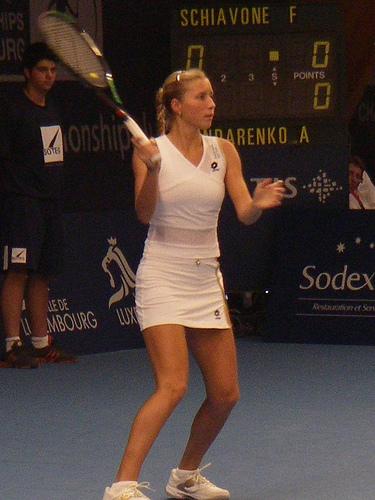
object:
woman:
[94, 67, 285, 497]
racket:
[32, 6, 163, 173]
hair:
[155, 67, 202, 135]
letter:
[300, 124, 309, 144]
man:
[3, 46, 77, 367]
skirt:
[132, 251, 233, 332]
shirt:
[0, 89, 71, 205]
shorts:
[0, 202, 58, 275]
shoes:
[36, 340, 81, 366]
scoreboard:
[169, 7, 352, 231]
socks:
[175, 468, 193, 475]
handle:
[124, 113, 161, 167]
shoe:
[167, 458, 229, 499]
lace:
[192, 460, 213, 477]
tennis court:
[0, 5, 369, 499]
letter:
[299, 265, 316, 290]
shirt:
[139, 129, 227, 261]